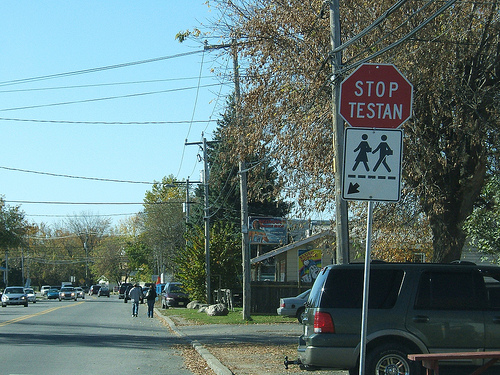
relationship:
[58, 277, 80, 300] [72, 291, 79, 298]
car with headlight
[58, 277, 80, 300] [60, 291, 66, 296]
car with headlight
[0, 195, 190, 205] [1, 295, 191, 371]
power line over street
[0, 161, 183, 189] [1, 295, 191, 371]
power line over street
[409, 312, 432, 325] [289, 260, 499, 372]
door handle on suv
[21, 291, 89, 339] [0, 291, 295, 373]
lines on ground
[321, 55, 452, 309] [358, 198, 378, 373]
sign on pole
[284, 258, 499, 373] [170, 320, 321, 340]
car on driveway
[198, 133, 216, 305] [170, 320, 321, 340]
pole on driveway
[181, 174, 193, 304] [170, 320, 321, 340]
pole on driveway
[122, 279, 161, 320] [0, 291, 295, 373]
people walking in ground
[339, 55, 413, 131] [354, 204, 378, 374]
sign on pole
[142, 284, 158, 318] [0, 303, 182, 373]
people walking down street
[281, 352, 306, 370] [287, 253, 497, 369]
hitch on back suv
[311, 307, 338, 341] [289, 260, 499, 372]
tail light on suv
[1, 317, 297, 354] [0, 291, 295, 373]
shadow on ground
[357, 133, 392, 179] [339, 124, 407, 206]
pedestrians on sign